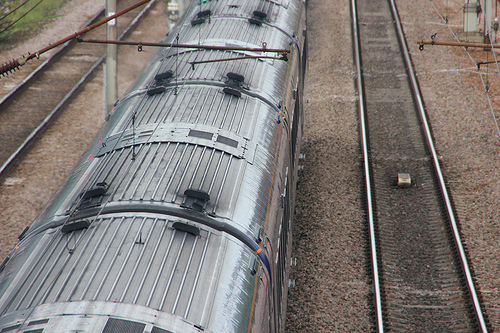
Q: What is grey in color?
A: Train.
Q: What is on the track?
A: The train.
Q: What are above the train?
A: Rusty bars.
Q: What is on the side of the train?
A: Yellow stripe.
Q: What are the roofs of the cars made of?
A: Metal.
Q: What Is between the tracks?
A: A train.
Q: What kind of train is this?
A: A passenger.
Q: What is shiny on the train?
A: The roof.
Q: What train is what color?
A: Silver.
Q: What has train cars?
A: The train.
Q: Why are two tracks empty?
A: No trains.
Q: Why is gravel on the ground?
A: To support the tracks.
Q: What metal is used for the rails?
A: Steel.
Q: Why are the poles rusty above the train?
A: Weathered.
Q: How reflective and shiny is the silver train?
A: Very reflective and shiny.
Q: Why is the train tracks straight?
A: To keep the train straight.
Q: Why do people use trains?
A: For transportation.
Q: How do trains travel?
A: On tracks.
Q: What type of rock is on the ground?
A: Gravel.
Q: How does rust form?
A: Water and weather.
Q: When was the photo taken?
A: Daytime.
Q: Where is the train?
A: On the tracks.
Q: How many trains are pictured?
A: One.